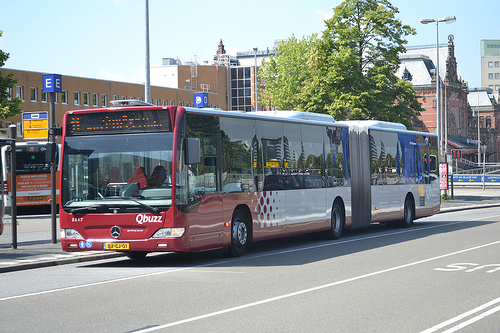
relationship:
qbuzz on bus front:
[134, 212, 166, 229] [60, 100, 443, 242]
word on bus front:
[122, 209, 166, 230] [60, 100, 443, 242]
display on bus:
[68, 110, 173, 135] [50, 100, 443, 263]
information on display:
[91, 119, 145, 124] [68, 110, 173, 135]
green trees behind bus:
[251, 6, 428, 121] [60, 80, 421, 277]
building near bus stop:
[3, 55, 233, 121] [16, 73, 120, 243]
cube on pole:
[43, 72, 63, 92] [48, 91, 56, 244]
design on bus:
[212, 192, 316, 234] [348, 129, 475, 215]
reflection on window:
[186, 117, 346, 189] [175, 112, 349, 212]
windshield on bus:
[54, 130, 178, 216] [50, 100, 443, 263]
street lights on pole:
[415, 5, 461, 200] [422, 55, 467, 225]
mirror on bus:
[186, 137, 200, 166] [36, 111, 478, 266]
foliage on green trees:
[268, 68, 306, 102] [251, 0, 420, 121]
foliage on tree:
[268, 68, 306, 102] [253, 30, 323, 112]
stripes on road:
[262, 264, 430, 288] [202, 227, 497, 321]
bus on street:
[50, 100, 443, 263] [1, 202, 498, 331]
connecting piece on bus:
[350, 123, 370, 230] [50, 100, 443, 263]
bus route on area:
[86, 111, 166, 132] [65, 109, 220, 166]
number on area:
[66, 113, 78, 129] [65, 109, 220, 166]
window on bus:
[220, 114, 345, 189] [50, 100, 443, 263]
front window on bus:
[60, 133, 179, 211] [50, 100, 443, 263]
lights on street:
[418, 12, 456, 28] [232, 262, 448, 327]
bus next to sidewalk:
[50, 100, 443, 263] [8, 233, 53, 260]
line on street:
[145, 252, 322, 324] [15, 229, 499, 329]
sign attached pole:
[25, 51, 89, 108] [22, 67, 107, 212]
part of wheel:
[340, 221, 347, 229] [325, 191, 355, 250]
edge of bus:
[344, 123, 351, 228] [102, 112, 410, 212]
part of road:
[396, 249, 419, 284] [9, 197, 494, 331]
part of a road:
[290, 267, 330, 311] [9, 197, 494, 331]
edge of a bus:
[344, 123, 351, 228] [50, 100, 443, 263]